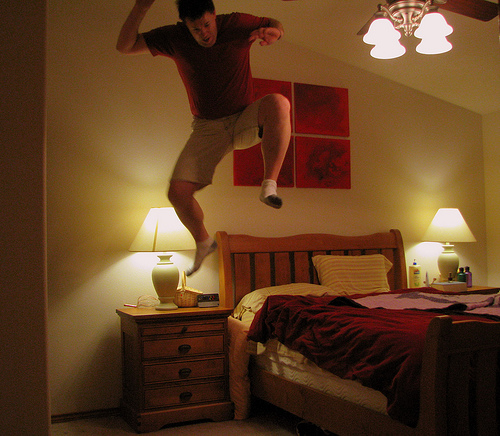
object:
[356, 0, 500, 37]
ceiling fan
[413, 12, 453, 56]
lights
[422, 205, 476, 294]
lamp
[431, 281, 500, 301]
nightstand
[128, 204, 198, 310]
lamp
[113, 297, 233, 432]
nightstand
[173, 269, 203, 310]
basket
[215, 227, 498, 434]
bed frame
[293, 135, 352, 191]
picture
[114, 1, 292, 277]
man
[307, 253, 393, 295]
pillow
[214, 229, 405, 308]
headboard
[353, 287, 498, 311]
blanket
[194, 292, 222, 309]
alarm clock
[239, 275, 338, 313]
pillow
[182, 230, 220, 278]
socks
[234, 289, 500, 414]
mattress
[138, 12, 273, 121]
shirt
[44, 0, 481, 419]
wall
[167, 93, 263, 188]
shorts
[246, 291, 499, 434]
blanket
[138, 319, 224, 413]
drawers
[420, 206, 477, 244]
shades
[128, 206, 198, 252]
shades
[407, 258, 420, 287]
lotion